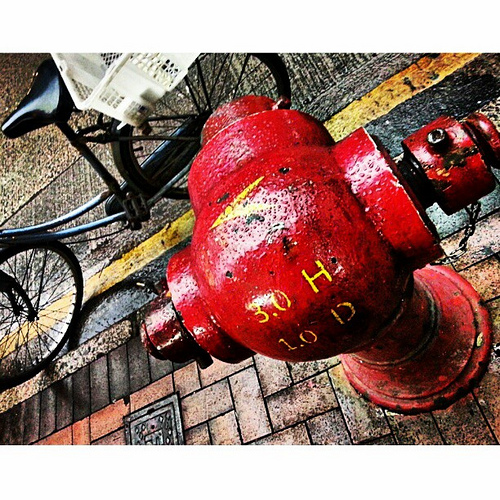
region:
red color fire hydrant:
[123, 122, 486, 413]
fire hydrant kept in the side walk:
[133, 135, 499, 437]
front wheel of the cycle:
[1, 222, 106, 421]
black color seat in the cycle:
[1, 56, 77, 146]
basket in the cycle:
[41, 55, 207, 114]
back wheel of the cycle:
[97, 56, 270, 191]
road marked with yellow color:
[78, 209, 199, 307]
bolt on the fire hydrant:
[425, 123, 452, 150]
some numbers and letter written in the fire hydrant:
[236, 256, 363, 354]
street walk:
[46, 355, 292, 449]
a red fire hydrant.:
[101, 32, 493, 431]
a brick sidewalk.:
[6, 222, 497, 467]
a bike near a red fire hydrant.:
[1, 25, 312, 391]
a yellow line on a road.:
[1, 45, 481, 365]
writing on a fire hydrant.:
[251, 236, 351, 379]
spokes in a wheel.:
[7, 245, 74, 347]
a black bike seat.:
[0, 71, 80, 158]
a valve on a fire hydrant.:
[361, 103, 498, 215]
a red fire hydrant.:
[126, 71, 340, 248]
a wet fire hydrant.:
[212, 180, 326, 276]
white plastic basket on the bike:
[46, 53, 199, 128]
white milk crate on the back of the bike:
[48, 55, 199, 125]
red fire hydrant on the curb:
[140, 94, 494, 411]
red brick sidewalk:
[2, 212, 498, 447]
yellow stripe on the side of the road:
[1, 50, 481, 355]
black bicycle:
[0, 57, 291, 392]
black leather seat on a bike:
[5, 68, 66, 135]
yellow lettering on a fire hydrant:
[253, 261, 354, 352]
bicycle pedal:
[125, 194, 153, 230]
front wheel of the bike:
[3, 236, 85, 386]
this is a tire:
[0, 218, 94, 425]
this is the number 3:
[236, 296, 272, 327]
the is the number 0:
[265, 283, 295, 316]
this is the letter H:
[298, 255, 338, 297]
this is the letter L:
[271, 333, 305, 365]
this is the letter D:
[308, 290, 383, 344]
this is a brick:
[223, 370, 282, 442]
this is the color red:
[258, 216, 273, 224]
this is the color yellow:
[308, 278, 312, 283]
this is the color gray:
[75, 393, 85, 398]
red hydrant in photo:
[108, 56, 430, 343]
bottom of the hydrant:
[434, 295, 478, 392]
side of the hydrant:
[116, 250, 202, 378]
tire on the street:
[0, 235, 90, 340]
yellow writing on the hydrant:
[226, 242, 351, 385]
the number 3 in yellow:
[238, 292, 270, 339]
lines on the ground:
[203, 370, 278, 444]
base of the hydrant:
[383, 315, 490, 432]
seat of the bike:
[12, 60, 82, 147]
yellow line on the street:
[366, 60, 432, 130]